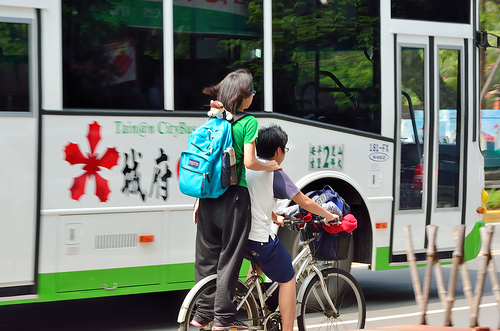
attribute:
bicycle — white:
[175, 214, 367, 331]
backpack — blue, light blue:
[178, 118, 238, 198]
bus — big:
[1, 0, 486, 306]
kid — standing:
[193, 69, 280, 330]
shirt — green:
[225, 112, 256, 184]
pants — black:
[197, 194, 246, 315]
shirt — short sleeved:
[246, 159, 300, 238]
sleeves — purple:
[273, 169, 299, 200]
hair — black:
[257, 126, 287, 157]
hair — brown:
[203, 69, 253, 109]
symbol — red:
[63, 121, 120, 203]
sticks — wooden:
[402, 222, 499, 326]